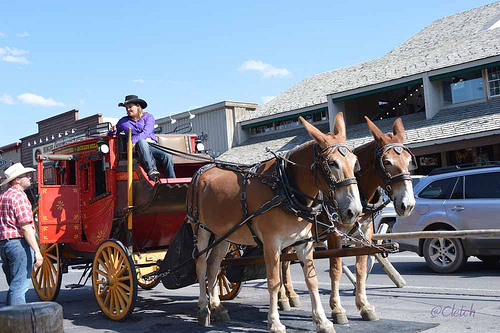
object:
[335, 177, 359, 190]
harness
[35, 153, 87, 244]
door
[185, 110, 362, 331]
horse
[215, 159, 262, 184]
mules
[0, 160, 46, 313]
person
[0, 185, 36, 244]
shirt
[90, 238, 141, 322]
wheel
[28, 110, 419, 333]
stagecoach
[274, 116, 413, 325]
horse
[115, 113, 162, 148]
shirt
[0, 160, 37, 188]
cowboy hat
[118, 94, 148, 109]
hat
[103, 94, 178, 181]
man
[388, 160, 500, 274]
car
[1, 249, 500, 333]
street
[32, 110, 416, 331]
carriage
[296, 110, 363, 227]
heads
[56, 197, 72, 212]
designs